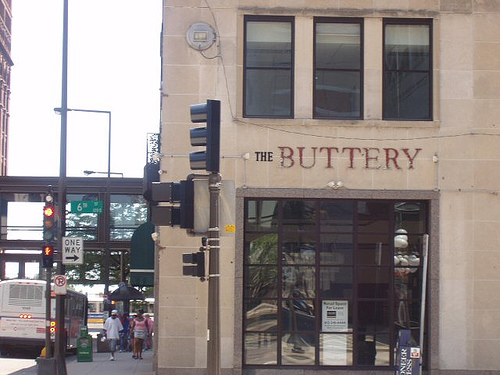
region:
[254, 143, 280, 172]
Black 'The' lettering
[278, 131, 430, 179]
Red lettering on grey building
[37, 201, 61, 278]
Black street lamp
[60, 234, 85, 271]
Black and white one way sign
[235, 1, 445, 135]
Three windows on top story of building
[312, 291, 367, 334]
Black and white sign on door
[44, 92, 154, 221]
Two grey street lamps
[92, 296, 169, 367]
Couple walking down the sidewalk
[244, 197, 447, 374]
brown trim on door of building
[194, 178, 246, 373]
Brown pole next to grey building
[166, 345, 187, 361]
tan paint on wall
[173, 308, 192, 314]
tan paint on wall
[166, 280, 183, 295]
tan paint on wall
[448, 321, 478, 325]
tan paint on wall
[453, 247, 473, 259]
tan paint on wall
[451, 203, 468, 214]
tan paint on wall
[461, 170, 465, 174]
tan paint on wall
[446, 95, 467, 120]
tan paint on wall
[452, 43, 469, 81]
tan paint on wall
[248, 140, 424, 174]
this establishment is called The Buttery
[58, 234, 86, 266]
a one way sign tells traffic to only go right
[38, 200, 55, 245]
the traffic light nearby is red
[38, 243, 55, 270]
the red hand on the walk/don't walk sign means don't walk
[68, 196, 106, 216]
a street sign for 6th Street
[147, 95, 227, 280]
the street lights for the cross street seen in profile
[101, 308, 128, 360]
this pedestrian is wearing a big white top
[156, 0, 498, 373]
The Buttery is on the bottom floor of a 2-story building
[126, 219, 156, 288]
a green awning can be seen around the corner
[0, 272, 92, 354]
a bus is stopped at the curb